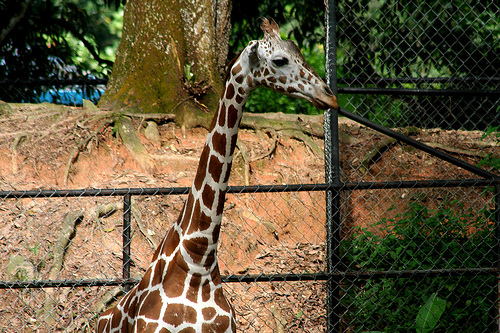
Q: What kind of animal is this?
A: Giraffe.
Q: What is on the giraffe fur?
A: Brown spots.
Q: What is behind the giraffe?
A: Fence.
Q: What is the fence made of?
A: Chain link metal fence.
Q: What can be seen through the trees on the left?
A: Blue vehicle.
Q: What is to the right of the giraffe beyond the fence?
A: Bushes and green foliage.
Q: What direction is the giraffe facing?
A: Right.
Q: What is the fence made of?
A: Metal.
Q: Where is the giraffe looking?
A: Right.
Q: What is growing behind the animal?
A: Tree.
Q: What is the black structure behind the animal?
A: Fence.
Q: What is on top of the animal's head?
A: Ossicones.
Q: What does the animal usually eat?
A: Leaves.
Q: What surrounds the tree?
A: Fence.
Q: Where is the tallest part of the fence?
A: Right.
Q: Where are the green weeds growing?
A: Right.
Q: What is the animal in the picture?
A: Giraffe.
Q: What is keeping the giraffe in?
A: Fence.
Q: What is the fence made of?
A: Metal.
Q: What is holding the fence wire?
A: Poles.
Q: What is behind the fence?
A: Bushes.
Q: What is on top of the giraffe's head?
A: Horns.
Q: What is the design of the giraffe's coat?
A: Spotted.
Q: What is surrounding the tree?
A: Dirt.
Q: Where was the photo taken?
A: Zoo.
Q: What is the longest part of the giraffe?
A: Neck.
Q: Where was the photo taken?
A: At a zoo.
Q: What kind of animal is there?
A: A giraffe.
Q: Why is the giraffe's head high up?
A: Its neck is long.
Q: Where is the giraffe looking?
A: To the right.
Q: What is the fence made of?
A: Metal.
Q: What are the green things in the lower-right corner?
A: Bushes.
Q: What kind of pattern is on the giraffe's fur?
A: Spots.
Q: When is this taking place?
A: Daytime.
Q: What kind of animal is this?
A: Giraffe.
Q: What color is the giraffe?
A: Brown and tan.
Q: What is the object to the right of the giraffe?
A: Fence.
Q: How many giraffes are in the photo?
A: One.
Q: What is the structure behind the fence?
A: Wall.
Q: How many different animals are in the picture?
A: One.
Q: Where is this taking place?
A: At the zoo.